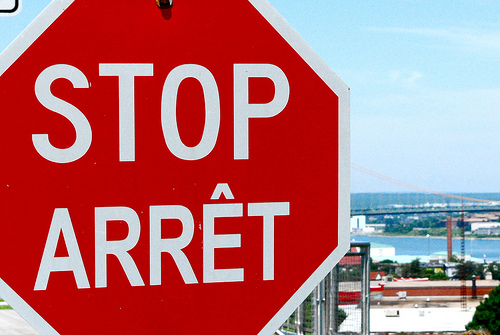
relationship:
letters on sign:
[22, 62, 297, 294] [1, 2, 355, 335]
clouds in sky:
[361, 17, 497, 53] [1, 1, 500, 197]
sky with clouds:
[1, 1, 500, 197] [361, 17, 497, 53]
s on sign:
[26, 60, 98, 174] [1, 2, 355, 335]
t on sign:
[95, 58, 156, 168] [1, 2, 355, 335]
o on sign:
[157, 62, 223, 163] [1, 2, 355, 335]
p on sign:
[230, 60, 293, 164] [1, 2, 355, 335]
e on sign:
[197, 199, 245, 290] [1, 2, 355, 335]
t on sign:
[244, 199, 292, 284] [1, 2, 355, 335]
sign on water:
[1, 2, 355, 335] [351, 229, 500, 265]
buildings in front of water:
[356, 199, 500, 240] [351, 229, 500, 265]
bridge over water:
[345, 162, 500, 262] [351, 229, 500, 265]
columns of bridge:
[446, 216, 455, 265] [345, 162, 500, 262]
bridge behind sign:
[345, 162, 500, 262] [1, 2, 355, 335]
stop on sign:
[28, 55, 291, 166] [1, 2, 355, 335]